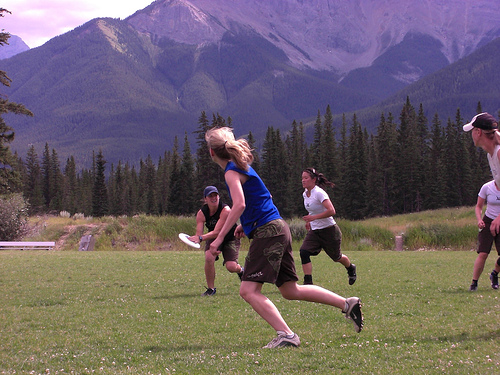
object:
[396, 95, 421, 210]
tree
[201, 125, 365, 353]
women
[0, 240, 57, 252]
bench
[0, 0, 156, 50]
sky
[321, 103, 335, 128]
top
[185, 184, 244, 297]
woman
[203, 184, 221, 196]
cap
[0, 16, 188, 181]
mountain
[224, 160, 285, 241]
shirt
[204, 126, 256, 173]
hair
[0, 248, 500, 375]
grass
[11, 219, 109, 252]
celte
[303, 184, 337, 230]
shirt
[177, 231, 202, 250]
frisbee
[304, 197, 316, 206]
nike